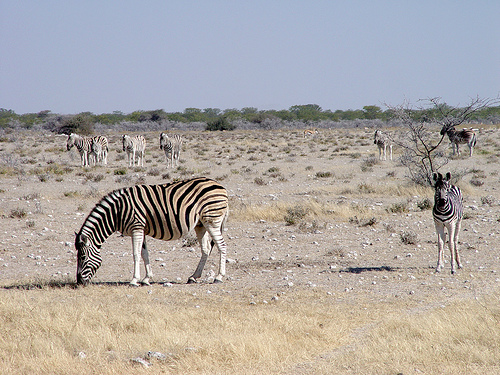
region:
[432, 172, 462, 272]
baby zebra standing up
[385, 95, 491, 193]
a tree with no leaves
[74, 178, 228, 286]
the zebra is grazing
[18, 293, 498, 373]
a patch of dead grass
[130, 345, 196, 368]
white rocks in the dead grass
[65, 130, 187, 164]
group of zebra standing together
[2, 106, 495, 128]
green trees on the horizon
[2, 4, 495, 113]
clear blue skies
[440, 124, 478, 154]
zebra standing behind the tree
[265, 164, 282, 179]
small bushes in the dirt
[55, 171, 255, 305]
this is a zebra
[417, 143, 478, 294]
this is a zebra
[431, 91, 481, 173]
this is a zebra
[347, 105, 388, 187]
this is a zebra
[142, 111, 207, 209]
this is a zebra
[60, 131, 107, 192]
this is a zebra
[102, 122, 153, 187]
this is a zebra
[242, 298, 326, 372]
this is a patch of grass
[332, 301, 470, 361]
this is a patch of grass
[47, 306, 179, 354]
this is a patch of grass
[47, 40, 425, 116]
the sky is overcast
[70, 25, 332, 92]
the sky is overcast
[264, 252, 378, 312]
rocks on the ground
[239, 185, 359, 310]
rocks on the ground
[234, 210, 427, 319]
rocks on the ground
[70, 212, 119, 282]
head of a zebra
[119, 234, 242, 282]
legs of a zebra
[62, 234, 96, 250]
ear of a zebra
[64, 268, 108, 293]
mouth of a zebra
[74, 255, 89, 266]
eye of a zebra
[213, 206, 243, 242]
tail of a zebra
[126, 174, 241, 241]
the body of a zebra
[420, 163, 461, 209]
head of a zebra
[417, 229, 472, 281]
legs of a zebra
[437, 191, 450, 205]
mouth of a zebra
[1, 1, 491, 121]
blue-gray sky over trees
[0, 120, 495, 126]
line of gray brush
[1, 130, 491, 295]
dry gray ground with tufts of grass and white stones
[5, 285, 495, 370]
short tan grass covering ground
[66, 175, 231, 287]
zebra bending neck to graze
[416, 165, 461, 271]
young zebra with pale legs standing still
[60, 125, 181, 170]
four zebras standing together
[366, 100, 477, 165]
zebras in back of leafless tree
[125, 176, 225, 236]
black and brown lines on body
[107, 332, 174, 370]
flat gray stones on grass